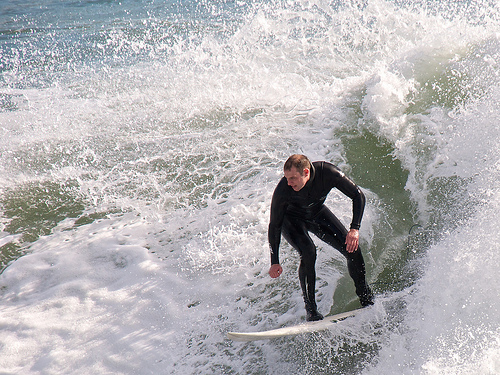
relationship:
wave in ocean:
[9, 37, 498, 372] [2, 0, 499, 373]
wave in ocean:
[0, 0, 498, 374] [8, 4, 150, 136]